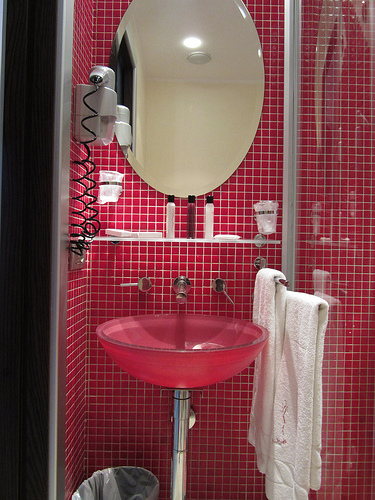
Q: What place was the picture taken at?
A: It was taken at the restroom.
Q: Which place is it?
A: It is a restroom.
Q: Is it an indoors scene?
A: Yes, it is indoors.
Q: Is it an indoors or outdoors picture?
A: It is indoors.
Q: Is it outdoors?
A: No, it is indoors.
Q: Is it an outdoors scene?
A: No, it is indoors.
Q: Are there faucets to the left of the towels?
A: Yes, there is a faucet to the left of the towels.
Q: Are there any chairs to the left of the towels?
A: No, there is a faucet to the left of the towels.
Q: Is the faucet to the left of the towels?
A: Yes, the faucet is to the left of the towels.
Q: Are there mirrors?
A: Yes, there is a mirror.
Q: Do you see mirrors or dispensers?
A: Yes, there is a mirror.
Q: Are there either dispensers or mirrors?
A: Yes, there is a mirror.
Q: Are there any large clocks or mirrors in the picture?
A: Yes, there is a large mirror.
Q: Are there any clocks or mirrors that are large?
A: Yes, the mirror is large.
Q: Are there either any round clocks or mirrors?
A: Yes, there is a round mirror.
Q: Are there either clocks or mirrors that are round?
A: Yes, the mirror is round.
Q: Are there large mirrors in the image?
A: Yes, there is a large mirror.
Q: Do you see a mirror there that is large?
A: Yes, there is a mirror that is large.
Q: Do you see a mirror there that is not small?
A: Yes, there is a large mirror.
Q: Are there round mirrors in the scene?
A: Yes, there is a round mirror.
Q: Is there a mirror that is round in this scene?
A: Yes, there is a round mirror.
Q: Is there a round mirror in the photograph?
A: Yes, there is a round mirror.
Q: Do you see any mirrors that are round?
A: Yes, there is a mirror that is round.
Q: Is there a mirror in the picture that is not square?
A: Yes, there is a round mirror.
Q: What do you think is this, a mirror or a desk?
A: This is a mirror.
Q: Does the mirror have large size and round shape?
A: Yes, the mirror is large and round.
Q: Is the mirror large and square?
A: No, the mirror is large but round.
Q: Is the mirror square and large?
A: No, the mirror is large but round.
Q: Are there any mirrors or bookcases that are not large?
A: No, there is a mirror but it is large.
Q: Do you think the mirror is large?
A: Yes, the mirror is large.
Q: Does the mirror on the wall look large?
A: Yes, the mirror is large.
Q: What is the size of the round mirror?
A: The mirror is large.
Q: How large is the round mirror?
A: The mirror is large.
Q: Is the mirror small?
A: No, the mirror is large.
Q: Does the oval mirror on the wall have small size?
A: No, the mirror is large.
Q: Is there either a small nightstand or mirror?
A: No, there is a mirror but it is large.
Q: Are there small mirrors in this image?
A: No, there is a mirror but it is large.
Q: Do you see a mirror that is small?
A: No, there is a mirror but it is large.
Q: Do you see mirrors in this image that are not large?
A: No, there is a mirror but it is large.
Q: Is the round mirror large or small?
A: The mirror is large.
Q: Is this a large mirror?
A: Yes, this is a large mirror.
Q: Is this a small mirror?
A: No, this is a large mirror.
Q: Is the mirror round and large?
A: Yes, the mirror is round and large.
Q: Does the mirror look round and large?
A: Yes, the mirror is round and large.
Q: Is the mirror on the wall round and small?
A: No, the mirror is round but large.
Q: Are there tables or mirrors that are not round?
A: No, there is a mirror but it is round.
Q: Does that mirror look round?
A: Yes, the mirror is round.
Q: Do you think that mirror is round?
A: Yes, the mirror is round.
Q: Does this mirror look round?
A: Yes, the mirror is round.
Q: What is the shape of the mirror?
A: The mirror is round.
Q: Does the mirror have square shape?
A: No, the mirror is round.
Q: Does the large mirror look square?
A: No, the mirror is round.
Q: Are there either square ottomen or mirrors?
A: No, there is a mirror but it is round.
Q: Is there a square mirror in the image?
A: No, there is a mirror but it is round.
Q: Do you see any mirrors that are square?
A: No, there is a mirror but it is round.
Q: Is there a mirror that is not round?
A: No, there is a mirror but it is round.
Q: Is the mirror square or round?
A: The mirror is round.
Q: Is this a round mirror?
A: Yes, this is a round mirror.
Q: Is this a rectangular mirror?
A: No, this is a round mirror.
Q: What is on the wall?
A: The mirror is on the wall.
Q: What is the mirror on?
A: The mirror is on the wall.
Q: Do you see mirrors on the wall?
A: Yes, there is a mirror on the wall.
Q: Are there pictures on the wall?
A: No, there is a mirror on the wall.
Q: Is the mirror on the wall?
A: Yes, the mirror is on the wall.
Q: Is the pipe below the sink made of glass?
A: Yes, the pipe is below the sink.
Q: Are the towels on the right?
A: Yes, the towels are on the right of the image.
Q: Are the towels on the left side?
A: No, the towels are on the right of the image.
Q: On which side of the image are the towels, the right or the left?
A: The towels are on the right of the image.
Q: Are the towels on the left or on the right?
A: The towels are on the right of the image.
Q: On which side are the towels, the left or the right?
A: The towels are on the right of the image.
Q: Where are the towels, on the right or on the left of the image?
A: The towels are on the right of the image.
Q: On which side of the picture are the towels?
A: The towels are on the right of the image.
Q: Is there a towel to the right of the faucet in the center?
A: Yes, there are towels to the right of the faucet.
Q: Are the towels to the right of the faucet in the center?
A: Yes, the towels are to the right of the faucet.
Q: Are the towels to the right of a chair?
A: No, the towels are to the right of the faucet.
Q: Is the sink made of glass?
A: Yes, the sink is made of glass.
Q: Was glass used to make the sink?
A: Yes, the sink is made of glass.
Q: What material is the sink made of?
A: The sink is made of glass.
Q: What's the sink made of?
A: The sink is made of glass.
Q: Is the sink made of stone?
A: No, the sink is made of glass.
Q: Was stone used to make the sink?
A: No, the sink is made of glass.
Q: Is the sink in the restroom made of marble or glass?
A: The sink is made of glass.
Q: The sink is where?
A: The sink is in the restroom.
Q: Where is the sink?
A: The sink is in the restroom.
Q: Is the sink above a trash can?
A: Yes, the sink is above a trash can.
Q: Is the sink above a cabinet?
A: No, the sink is above a trash can.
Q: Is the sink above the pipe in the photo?
A: Yes, the sink is above the pipe.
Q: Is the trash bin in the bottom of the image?
A: Yes, the trash bin is in the bottom of the image.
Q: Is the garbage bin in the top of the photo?
A: No, the garbage bin is in the bottom of the image.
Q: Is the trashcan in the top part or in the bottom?
A: The trashcan is in the bottom of the image.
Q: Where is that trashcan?
A: The trashcan is in the restroom.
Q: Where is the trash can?
A: The trashcan is in the restroom.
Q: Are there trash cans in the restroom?
A: Yes, there is a trash can in the restroom.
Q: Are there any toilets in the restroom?
A: No, there is a trash can in the restroom.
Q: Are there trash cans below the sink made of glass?
A: Yes, there is a trash can below the sink.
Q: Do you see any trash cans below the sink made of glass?
A: Yes, there is a trash can below the sink.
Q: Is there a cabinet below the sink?
A: No, there is a trash can below the sink.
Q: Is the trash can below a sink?
A: Yes, the trash can is below a sink.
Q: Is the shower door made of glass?
A: Yes, the shower door is made of glass.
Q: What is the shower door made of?
A: The shower door is made of glass.